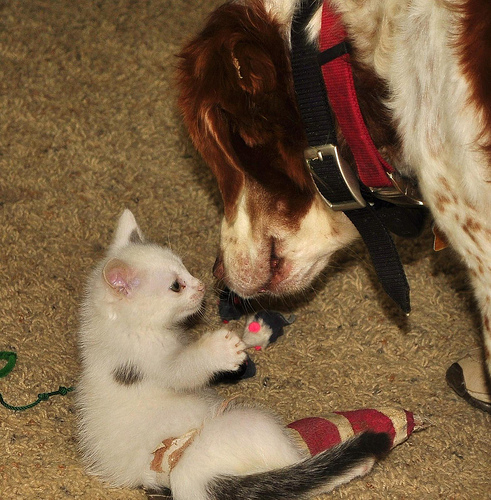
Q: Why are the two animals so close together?
A: They are playing with each other.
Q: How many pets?
A: Two.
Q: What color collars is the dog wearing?
A: Red one and a black one.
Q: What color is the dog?
A: Brown and white.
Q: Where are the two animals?
A: Laying on carpet.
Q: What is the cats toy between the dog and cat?
A: A mouse.